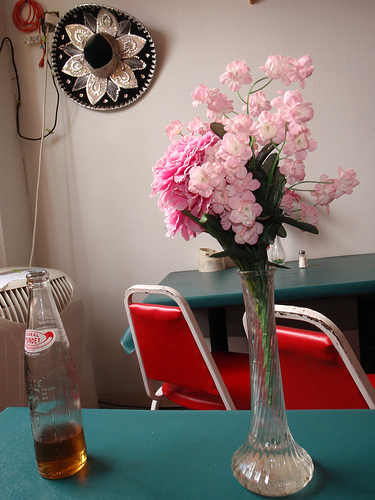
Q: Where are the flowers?
A: In the vase.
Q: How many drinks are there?
A: One.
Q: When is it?
A: Day time.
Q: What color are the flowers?
A: Pink.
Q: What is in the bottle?
A: Soda.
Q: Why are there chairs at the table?
A: It is a restaurant.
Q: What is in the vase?
A: Flowers.